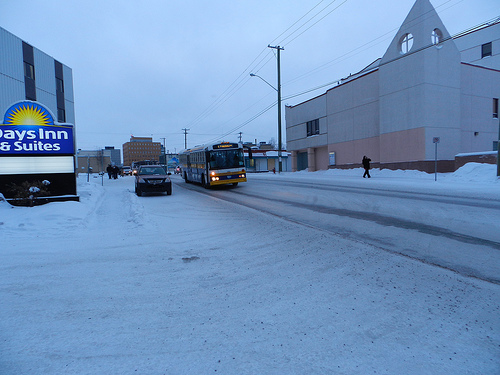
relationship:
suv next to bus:
[132, 164, 174, 197] [173, 136, 250, 187]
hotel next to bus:
[1, 29, 81, 182] [173, 136, 250, 187]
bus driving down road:
[173, 136, 250, 187] [104, 165, 499, 375]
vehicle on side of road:
[123, 164, 132, 177] [104, 165, 499, 375]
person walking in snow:
[358, 155, 376, 179] [1, 159, 499, 375]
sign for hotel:
[1, 99, 77, 177] [1, 29, 81, 182]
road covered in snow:
[104, 165, 499, 375] [1, 159, 499, 375]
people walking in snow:
[105, 160, 123, 180] [1, 159, 499, 375]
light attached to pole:
[246, 72, 257, 78] [275, 48, 283, 152]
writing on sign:
[1, 128, 69, 154] [1, 99, 77, 177]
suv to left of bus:
[132, 164, 174, 197] [173, 136, 250, 187]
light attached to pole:
[246, 72, 257, 80] [275, 48, 283, 152]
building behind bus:
[122, 136, 167, 171] [173, 136, 250, 187]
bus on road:
[173, 136, 250, 187] [104, 165, 499, 375]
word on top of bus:
[216, 143, 234, 149] [173, 136, 250, 187]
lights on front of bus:
[210, 170, 221, 182] [173, 136, 250, 187]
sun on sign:
[7, 107, 51, 128] [1, 99, 77, 177]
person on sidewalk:
[358, 155, 376, 179] [253, 161, 499, 195]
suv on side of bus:
[132, 164, 174, 197] [173, 136, 250, 187]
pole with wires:
[275, 48, 283, 152] [186, 0, 351, 118]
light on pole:
[246, 72, 257, 80] [275, 48, 283, 152]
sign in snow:
[1, 99, 77, 177] [5, 202, 159, 283]